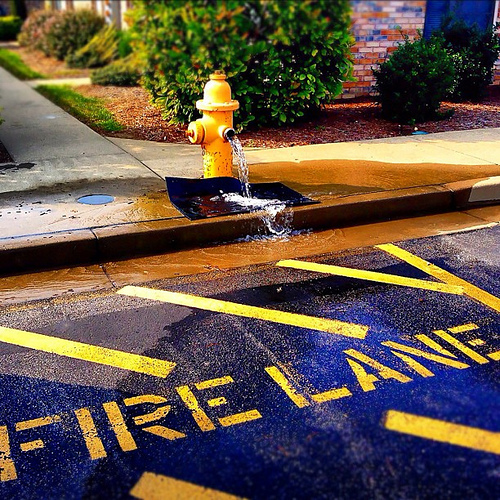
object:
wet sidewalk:
[182, 154, 411, 304]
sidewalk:
[1, 68, 496, 270]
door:
[420, 2, 499, 67]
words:
[0, 318, 499, 489]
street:
[2, 204, 499, 499]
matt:
[151, 160, 338, 212]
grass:
[0, 44, 125, 135]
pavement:
[0, 67, 85, 164]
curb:
[3, 162, 498, 278]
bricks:
[344, 14, 421, 100]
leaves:
[126, 0, 356, 126]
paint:
[206, 147, 231, 174]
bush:
[368, 33, 462, 125]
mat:
[161, 174, 321, 221]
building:
[0, 0, 500, 105]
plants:
[0, 1, 147, 91]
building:
[17, 0, 499, 120]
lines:
[0, 233, 499, 497]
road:
[0, 206, 499, 500]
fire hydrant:
[190, 69, 243, 184]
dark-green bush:
[428, 12, 498, 100]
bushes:
[18, 7, 137, 87]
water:
[206, 133, 367, 288]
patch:
[58, 176, 332, 239]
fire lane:
[0, 207, 500, 500]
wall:
[330, 1, 472, 105]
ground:
[0, 201, 499, 499]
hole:
[75, 190, 115, 206]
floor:
[178, 177, 307, 203]